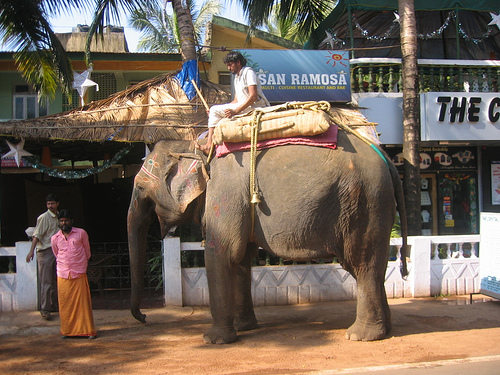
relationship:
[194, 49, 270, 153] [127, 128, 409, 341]
man on elephant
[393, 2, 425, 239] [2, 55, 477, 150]
tree in front of store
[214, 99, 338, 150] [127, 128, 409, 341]
saddle on elephant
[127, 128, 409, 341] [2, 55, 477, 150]
elephant by store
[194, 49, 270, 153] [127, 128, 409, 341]
man sitting on elephant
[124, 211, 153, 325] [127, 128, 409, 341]
trunk on elephant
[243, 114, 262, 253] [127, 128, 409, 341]
rope on elephant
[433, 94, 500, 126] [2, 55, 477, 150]
letters on store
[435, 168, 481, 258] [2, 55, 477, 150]
door on store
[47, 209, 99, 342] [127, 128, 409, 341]
person by elephant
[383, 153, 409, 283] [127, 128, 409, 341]
tail on elephant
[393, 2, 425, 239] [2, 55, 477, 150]
tree by store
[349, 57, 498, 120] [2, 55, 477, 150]
balcony above store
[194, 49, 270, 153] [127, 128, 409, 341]
man on top of elephant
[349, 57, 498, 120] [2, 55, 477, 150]
balcony over store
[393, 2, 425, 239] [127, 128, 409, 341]
tree behind elephant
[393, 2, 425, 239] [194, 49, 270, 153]
tree behind man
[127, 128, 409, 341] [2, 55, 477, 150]
elephant in front of store